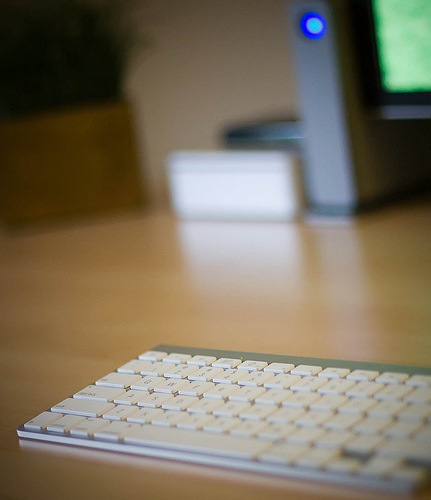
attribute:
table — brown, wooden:
[144, 246, 315, 314]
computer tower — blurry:
[283, 1, 425, 216]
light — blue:
[297, 10, 327, 40]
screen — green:
[380, 8, 427, 107]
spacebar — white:
[109, 421, 274, 472]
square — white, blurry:
[153, 138, 304, 234]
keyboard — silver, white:
[38, 310, 422, 499]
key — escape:
[134, 336, 167, 364]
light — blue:
[295, 7, 363, 43]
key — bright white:
[257, 383, 289, 405]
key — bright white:
[242, 402, 281, 420]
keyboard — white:
[8, 343, 429, 495]